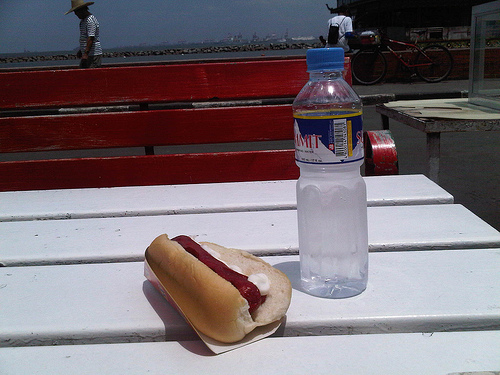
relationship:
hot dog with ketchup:
[147, 232, 293, 345] [172, 235, 258, 299]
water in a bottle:
[296, 159, 368, 297] [290, 47, 370, 298]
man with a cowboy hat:
[66, 2, 104, 65] [64, 1, 95, 16]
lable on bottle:
[291, 108, 364, 166] [290, 47, 370, 298]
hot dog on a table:
[147, 232, 293, 345] [1, 173, 500, 373]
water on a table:
[296, 159, 368, 297] [1, 173, 500, 373]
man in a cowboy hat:
[66, 2, 104, 65] [64, 1, 95, 16]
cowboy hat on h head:
[64, 1, 95, 16] [74, 6, 92, 20]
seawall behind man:
[1, 41, 329, 66] [66, 2, 104, 65]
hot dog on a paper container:
[147, 232, 293, 345] [143, 260, 282, 354]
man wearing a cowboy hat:
[66, 2, 104, 65] [64, 1, 95, 16]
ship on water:
[273, 36, 286, 44] [1, 41, 332, 72]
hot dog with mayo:
[147, 232, 293, 345] [201, 242, 273, 296]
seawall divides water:
[1, 41, 329, 66] [1, 41, 332, 72]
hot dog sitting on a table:
[147, 232, 293, 345] [1, 173, 500, 373]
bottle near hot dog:
[290, 47, 370, 298] [147, 232, 293, 345]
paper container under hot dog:
[143, 260, 282, 354] [147, 232, 293, 345]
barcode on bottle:
[334, 117, 347, 156] [290, 47, 370, 298]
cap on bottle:
[305, 48, 345, 71] [290, 47, 370, 298]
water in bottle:
[296, 159, 368, 297] [290, 47, 370, 298]